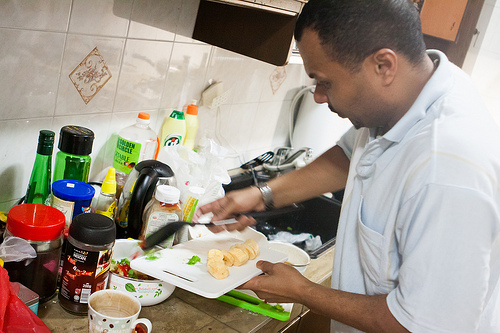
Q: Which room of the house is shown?
A: It is a kitchen.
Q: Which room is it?
A: It is a kitchen.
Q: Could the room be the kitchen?
A: Yes, it is the kitchen.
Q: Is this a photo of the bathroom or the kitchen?
A: It is showing the kitchen.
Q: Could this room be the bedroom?
A: No, it is the kitchen.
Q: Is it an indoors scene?
A: Yes, it is indoors.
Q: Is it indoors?
A: Yes, it is indoors.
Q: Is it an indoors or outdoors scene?
A: It is indoors.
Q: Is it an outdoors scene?
A: No, it is indoors.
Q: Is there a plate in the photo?
A: Yes, there is a plate.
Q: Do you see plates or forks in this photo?
A: Yes, there is a plate.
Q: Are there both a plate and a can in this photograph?
A: No, there is a plate but no cans.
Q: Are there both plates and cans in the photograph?
A: No, there is a plate but no cans.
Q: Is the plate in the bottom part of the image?
A: Yes, the plate is in the bottom of the image.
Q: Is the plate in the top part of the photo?
A: No, the plate is in the bottom of the image.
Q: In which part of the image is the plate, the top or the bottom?
A: The plate is in the bottom of the image.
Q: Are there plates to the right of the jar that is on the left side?
A: Yes, there is a plate to the right of the jar.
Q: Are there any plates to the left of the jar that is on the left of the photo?
A: No, the plate is to the right of the jar.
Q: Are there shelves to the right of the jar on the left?
A: No, there is a plate to the right of the jar.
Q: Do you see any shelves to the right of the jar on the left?
A: No, there is a plate to the right of the jar.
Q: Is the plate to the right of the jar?
A: Yes, the plate is to the right of the jar.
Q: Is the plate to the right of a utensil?
A: No, the plate is to the right of the jar.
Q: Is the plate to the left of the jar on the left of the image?
A: No, the plate is to the right of the jar.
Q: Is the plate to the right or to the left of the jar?
A: The plate is to the right of the jar.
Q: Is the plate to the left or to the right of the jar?
A: The plate is to the right of the jar.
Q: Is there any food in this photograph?
A: Yes, there is food.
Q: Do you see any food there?
A: Yes, there is food.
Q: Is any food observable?
A: Yes, there is food.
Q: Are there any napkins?
A: No, there are no napkins.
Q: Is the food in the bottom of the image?
A: Yes, the food is in the bottom of the image.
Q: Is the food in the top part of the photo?
A: No, the food is in the bottom of the image.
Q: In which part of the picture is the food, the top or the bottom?
A: The food is in the bottom of the image.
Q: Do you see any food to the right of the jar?
A: Yes, there is food to the right of the jar.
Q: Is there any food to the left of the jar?
A: No, the food is to the right of the jar.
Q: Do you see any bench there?
A: No, there are no benches.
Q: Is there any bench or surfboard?
A: No, there are no benches or surfboards.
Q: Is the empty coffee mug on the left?
A: Yes, the coffee mug is on the left of the image.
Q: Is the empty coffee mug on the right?
A: No, the coffee mug is on the left of the image.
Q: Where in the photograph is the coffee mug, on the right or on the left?
A: The coffee mug is on the left of the image.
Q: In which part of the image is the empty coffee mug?
A: The coffee mug is on the left of the image.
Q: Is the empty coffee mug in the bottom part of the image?
A: Yes, the coffee mug is in the bottom of the image.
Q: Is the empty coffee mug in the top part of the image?
A: No, the coffee mug is in the bottom of the image.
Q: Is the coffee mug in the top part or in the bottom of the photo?
A: The coffee mug is in the bottom of the image.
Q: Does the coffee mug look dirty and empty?
A: Yes, the coffee mug is dirty and empty.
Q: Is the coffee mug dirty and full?
A: No, the coffee mug is dirty but empty.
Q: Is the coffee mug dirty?
A: Yes, the coffee mug is dirty.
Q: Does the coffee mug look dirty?
A: Yes, the coffee mug is dirty.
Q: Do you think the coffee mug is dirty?
A: Yes, the coffee mug is dirty.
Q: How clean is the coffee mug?
A: The coffee mug is dirty.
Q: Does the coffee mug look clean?
A: No, the coffee mug is dirty.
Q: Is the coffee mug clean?
A: No, the coffee mug is dirty.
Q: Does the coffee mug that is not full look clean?
A: No, the coffee mug is dirty.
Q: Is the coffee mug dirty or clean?
A: The coffee mug is dirty.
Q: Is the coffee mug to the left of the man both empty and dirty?
A: Yes, the coffee mug is empty and dirty.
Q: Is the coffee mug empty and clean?
A: No, the coffee mug is empty but dirty.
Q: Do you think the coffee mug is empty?
A: Yes, the coffee mug is empty.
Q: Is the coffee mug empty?
A: Yes, the coffee mug is empty.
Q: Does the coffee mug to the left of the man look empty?
A: Yes, the coffee mug is empty.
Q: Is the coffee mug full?
A: No, the coffee mug is empty.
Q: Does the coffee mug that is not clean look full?
A: No, the coffee mug is empty.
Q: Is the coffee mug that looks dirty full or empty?
A: The coffee mug is empty.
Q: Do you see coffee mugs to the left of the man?
A: Yes, there is a coffee mug to the left of the man.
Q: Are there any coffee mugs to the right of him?
A: No, the coffee mug is to the left of the man.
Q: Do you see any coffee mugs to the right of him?
A: No, the coffee mug is to the left of the man.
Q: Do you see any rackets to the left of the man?
A: No, there is a coffee mug to the left of the man.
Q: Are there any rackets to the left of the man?
A: No, there is a coffee mug to the left of the man.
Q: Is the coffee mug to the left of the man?
A: Yes, the coffee mug is to the left of the man.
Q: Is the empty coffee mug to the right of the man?
A: No, the coffee mug is to the left of the man.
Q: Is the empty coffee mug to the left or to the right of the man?
A: The coffee mug is to the left of the man.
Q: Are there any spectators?
A: No, there are no spectators.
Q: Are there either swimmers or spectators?
A: No, there are no spectators or swimmers.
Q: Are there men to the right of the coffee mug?
A: Yes, there is a man to the right of the coffee mug.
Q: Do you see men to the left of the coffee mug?
A: No, the man is to the right of the coffee mug.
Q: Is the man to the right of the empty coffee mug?
A: Yes, the man is to the right of the coffee mug.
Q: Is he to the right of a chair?
A: No, the man is to the right of the coffee mug.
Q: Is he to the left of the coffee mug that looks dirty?
A: No, the man is to the right of the coffee mug.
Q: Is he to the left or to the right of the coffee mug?
A: The man is to the right of the coffee mug.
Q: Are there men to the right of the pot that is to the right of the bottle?
A: Yes, there is a man to the right of the pot.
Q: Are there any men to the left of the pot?
A: No, the man is to the right of the pot.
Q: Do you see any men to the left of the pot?
A: No, the man is to the right of the pot.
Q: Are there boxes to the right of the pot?
A: No, there is a man to the right of the pot.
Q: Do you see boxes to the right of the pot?
A: No, there is a man to the right of the pot.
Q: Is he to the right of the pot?
A: Yes, the man is to the right of the pot.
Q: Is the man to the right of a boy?
A: No, the man is to the right of the pot.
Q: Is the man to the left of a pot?
A: No, the man is to the right of a pot.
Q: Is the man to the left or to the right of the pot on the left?
A: The man is to the right of the pot.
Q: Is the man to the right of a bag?
A: No, the man is to the right of a bottle.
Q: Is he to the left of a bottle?
A: No, the man is to the right of a bottle.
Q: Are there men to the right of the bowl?
A: Yes, there is a man to the right of the bowl.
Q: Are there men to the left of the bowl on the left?
A: No, the man is to the right of the bowl.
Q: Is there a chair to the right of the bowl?
A: No, there is a man to the right of the bowl.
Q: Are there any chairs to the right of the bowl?
A: No, there is a man to the right of the bowl.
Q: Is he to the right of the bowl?
A: Yes, the man is to the right of the bowl.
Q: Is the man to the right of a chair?
A: No, the man is to the right of the bowl.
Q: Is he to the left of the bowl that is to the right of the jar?
A: No, the man is to the right of the bowl.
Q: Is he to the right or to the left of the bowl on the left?
A: The man is to the right of the bowl.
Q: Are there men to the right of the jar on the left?
A: Yes, there is a man to the right of the jar.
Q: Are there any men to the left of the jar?
A: No, the man is to the right of the jar.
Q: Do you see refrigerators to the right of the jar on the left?
A: No, there is a man to the right of the jar.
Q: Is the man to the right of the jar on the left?
A: Yes, the man is to the right of the jar.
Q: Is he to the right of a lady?
A: No, the man is to the right of the jar.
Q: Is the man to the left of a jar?
A: No, the man is to the right of a jar.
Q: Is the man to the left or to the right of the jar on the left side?
A: The man is to the right of the jar.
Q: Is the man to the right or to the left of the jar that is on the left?
A: The man is to the right of the jar.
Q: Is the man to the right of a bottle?
A: Yes, the man is to the right of a bottle.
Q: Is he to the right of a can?
A: No, the man is to the right of a bottle.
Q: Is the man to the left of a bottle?
A: No, the man is to the right of a bottle.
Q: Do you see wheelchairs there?
A: No, there are no wheelchairs.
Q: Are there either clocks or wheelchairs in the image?
A: No, there are no wheelchairs or clocks.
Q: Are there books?
A: No, there are no books.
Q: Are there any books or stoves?
A: No, there are no books or stoves.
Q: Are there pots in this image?
A: Yes, there is a pot.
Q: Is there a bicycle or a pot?
A: Yes, there is a pot.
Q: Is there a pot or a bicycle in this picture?
A: Yes, there is a pot.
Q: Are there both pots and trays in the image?
A: No, there is a pot but no trays.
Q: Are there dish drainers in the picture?
A: No, there are no dish drainers.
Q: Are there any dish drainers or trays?
A: No, there are no dish drainers or trays.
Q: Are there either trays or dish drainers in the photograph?
A: No, there are no dish drainers or trays.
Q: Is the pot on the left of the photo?
A: Yes, the pot is on the left of the image.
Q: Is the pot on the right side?
A: No, the pot is on the left of the image.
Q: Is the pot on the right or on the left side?
A: The pot is on the left of the image.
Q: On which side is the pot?
A: The pot is on the left of the image.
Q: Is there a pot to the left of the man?
A: Yes, there is a pot to the left of the man.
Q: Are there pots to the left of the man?
A: Yes, there is a pot to the left of the man.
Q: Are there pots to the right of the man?
A: No, the pot is to the left of the man.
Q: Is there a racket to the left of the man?
A: No, there is a pot to the left of the man.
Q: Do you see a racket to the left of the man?
A: No, there is a pot to the left of the man.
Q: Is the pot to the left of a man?
A: Yes, the pot is to the left of a man.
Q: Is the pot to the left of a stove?
A: No, the pot is to the left of a man.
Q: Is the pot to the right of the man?
A: No, the pot is to the left of the man.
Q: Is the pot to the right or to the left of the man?
A: The pot is to the left of the man.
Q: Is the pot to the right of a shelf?
A: No, the pot is to the right of the bottle.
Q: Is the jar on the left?
A: Yes, the jar is on the left of the image.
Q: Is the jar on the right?
A: No, the jar is on the left of the image.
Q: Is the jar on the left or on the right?
A: The jar is on the left of the image.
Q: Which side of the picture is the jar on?
A: The jar is on the left of the image.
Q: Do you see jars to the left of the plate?
A: Yes, there is a jar to the left of the plate.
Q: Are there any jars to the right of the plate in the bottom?
A: No, the jar is to the left of the plate.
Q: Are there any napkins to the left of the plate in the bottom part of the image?
A: No, there is a jar to the left of the plate.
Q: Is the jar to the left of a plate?
A: Yes, the jar is to the left of a plate.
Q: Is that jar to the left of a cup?
A: No, the jar is to the left of a plate.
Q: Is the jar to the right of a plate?
A: No, the jar is to the left of a plate.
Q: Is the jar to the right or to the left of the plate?
A: The jar is to the left of the plate.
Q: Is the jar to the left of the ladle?
A: Yes, the jar is to the left of the ladle.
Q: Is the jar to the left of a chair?
A: No, the jar is to the left of the ladle.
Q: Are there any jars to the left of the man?
A: Yes, there is a jar to the left of the man.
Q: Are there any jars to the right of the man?
A: No, the jar is to the left of the man.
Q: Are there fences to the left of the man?
A: No, there is a jar to the left of the man.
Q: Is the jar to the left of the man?
A: Yes, the jar is to the left of the man.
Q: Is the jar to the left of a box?
A: No, the jar is to the left of the man.